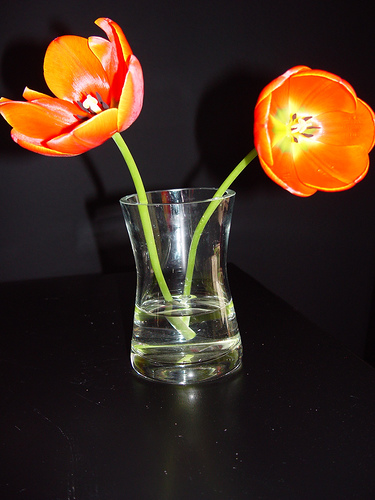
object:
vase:
[119, 185, 245, 385]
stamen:
[94, 90, 103, 102]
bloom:
[0, 12, 146, 154]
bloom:
[252, 63, 375, 198]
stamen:
[293, 136, 298, 144]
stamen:
[74, 113, 87, 122]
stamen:
[301, 132, 312, 138]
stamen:
[75, 97, 82, 109]